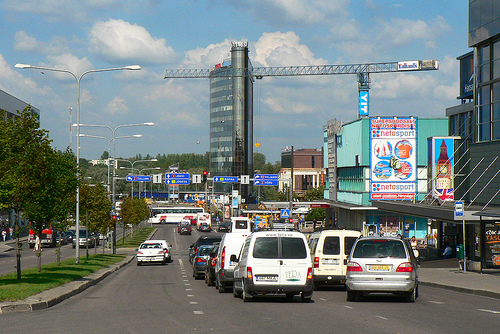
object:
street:
[2, 221, 499, 334]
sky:
[0, 1, 470, 163]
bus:
[148, 205, 204, 223]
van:
[342, 237, 421, 302]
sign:
[454, 199, 465, 220]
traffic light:
[202, 170, 207, 183]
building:
[323, 116, 450, 264]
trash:
[456, 243, 466, 260]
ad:
[369, 114, 418, 205]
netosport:
[381, 129, 416, 138]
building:
[205, 42, 253, 205]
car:
[135, 241, 167, 265]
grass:
[1, 254, 108, 302]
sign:
[126, 175, 151, 181]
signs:
[164, 172, 191, 185]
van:
[231, 230, 313, 300]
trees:
[1, 102, 49, 282]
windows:
[360, 167, 366, 190]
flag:
[433, 187, 454, 202]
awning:
[372, 198, 500, 221]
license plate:
[145, 257, 156, 260]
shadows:
[2, 271, 57, 287]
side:
[205, 68, 231, 198]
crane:
[164, 59, 438, 81]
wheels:
[345, 288, 357, 302]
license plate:
[368, 264, 393, 272]